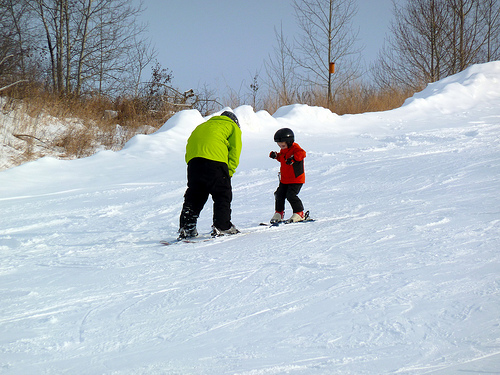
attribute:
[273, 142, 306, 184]
jacket — red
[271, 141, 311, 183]
jacket — red, long sleeved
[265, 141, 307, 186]
jacket — orange snow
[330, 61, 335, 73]
can — orange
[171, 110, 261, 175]
jacket — YELLOW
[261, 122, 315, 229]
child — young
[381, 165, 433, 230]
snow — white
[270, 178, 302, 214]
pants — black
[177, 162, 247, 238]
pants — snow pants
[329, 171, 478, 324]
snow — white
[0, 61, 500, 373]
snow — white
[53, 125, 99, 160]
bush — dead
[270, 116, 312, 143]
helmet — safety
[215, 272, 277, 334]
snow — white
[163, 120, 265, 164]
jacket — green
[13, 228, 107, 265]
snow — white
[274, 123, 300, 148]
helmet — black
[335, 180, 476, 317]
snow — large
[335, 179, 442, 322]
snow — white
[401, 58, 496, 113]
pile — large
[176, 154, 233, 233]
pants — black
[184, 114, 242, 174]
jacket — long sleeved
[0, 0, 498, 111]
trees — bare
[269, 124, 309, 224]
child — young